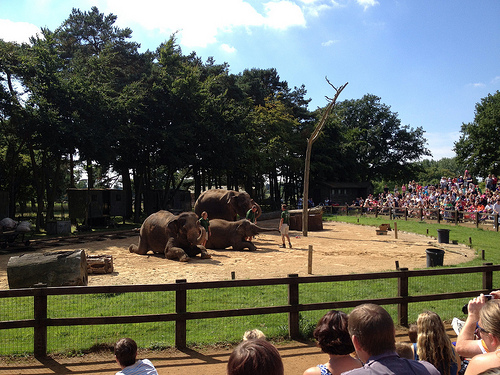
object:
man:
[339, 302, 439, 375]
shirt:
[342, 352, 442, 374]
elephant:
[194, 189, 262, 222]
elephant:
[206, 218, 284, 251]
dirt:
[2, 215, 481, 292]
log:
[7, 249, 89, 289]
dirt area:
[0, 219, 475, 289]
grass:
[1, 213, 498, 351]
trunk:
[195, 221, 206, 245]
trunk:
[259, 227, 281, 233]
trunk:
[253, 202, 262, 219]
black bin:
[436, 228, 451, 243]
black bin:
[425, 248, 445, 268]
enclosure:
[0, 201, 500, 358]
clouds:
[108, 1, 381, 54]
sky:
[141, 0, 496, 96]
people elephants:
[198, 211, 212, 247]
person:
[278, 203, 292, 248]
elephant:
[129, 210, 212, 262]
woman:
[411, 310, 460, 374]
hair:
[416, 312, 457, 375]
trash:
[426, 248, 445, 268]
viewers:
[6, 133, 499, 374]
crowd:
[372, 173, 497, 221]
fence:
[0, 260, 500, 362]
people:
[352, 175, 499, 218]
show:
[129, 188, 290, 263]